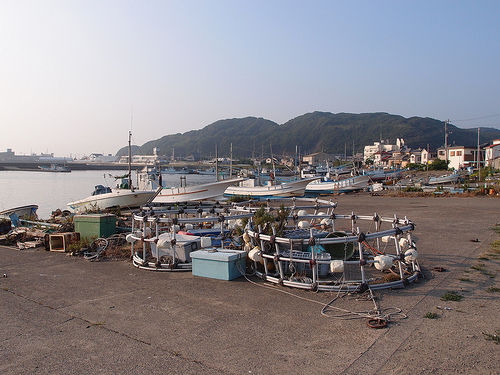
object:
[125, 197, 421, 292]
rings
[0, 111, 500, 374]
ground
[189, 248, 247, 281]
box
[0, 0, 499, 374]
bad statement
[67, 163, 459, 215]
ships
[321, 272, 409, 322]
rope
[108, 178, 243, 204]
boat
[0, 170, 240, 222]
water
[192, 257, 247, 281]
blue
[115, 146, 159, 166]
boat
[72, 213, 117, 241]
green box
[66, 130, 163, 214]
boat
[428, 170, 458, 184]
boat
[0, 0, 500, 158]
white clouds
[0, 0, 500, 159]
blue sky